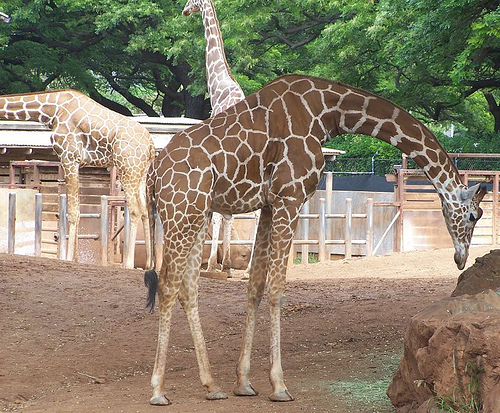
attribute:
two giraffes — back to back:
[2, 67, 484, 407]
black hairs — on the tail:
[143, 268, 158, 313]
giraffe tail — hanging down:
[143, 175, 166, 308]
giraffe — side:
[143, 85, 483, 385]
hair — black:
[141, 271, 158, 307]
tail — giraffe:
[144, 211, 161, 292]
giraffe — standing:
[140, 63, 490, 401]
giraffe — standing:
[0, 82, 158, 276]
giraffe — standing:
[178, 0, 294, 291]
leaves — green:
[375, 64, 412, 90]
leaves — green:
[274, 54, 424, 77]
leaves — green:
[168, 27, 198, 50]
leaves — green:
[472, 6, 496, 41]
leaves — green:
[66, 22, 166, 83]